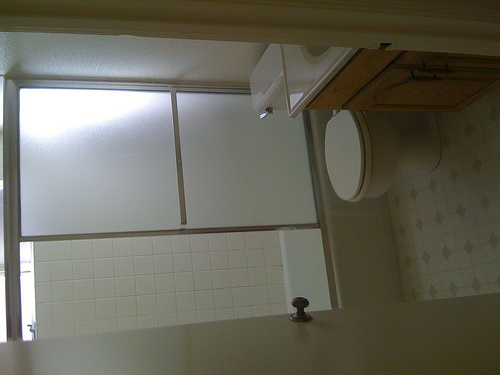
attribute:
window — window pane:
[7, 59, 453, 296]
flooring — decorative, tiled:
[336, 93, 499, 302]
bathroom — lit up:
[1, 27, 499, 338]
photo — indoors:
[0, 0, 499, 372]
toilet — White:
[245, 43, 447, 205]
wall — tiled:
[156, 201, 318, 313]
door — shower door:
[56, 123, 243, 232]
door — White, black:
[4, 294, 497, 367]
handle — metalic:
[283, 289, 317, 321]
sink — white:
[239, 66, 371, 106]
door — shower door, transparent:
[16, 83, 325, 243]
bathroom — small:
[7, 30, 495, 308]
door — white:
[23, 286, 481, 365]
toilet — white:
[323, 106, 443, 201]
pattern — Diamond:
[358, 97, 498, 304]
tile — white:
[30, 226, 296, 338]